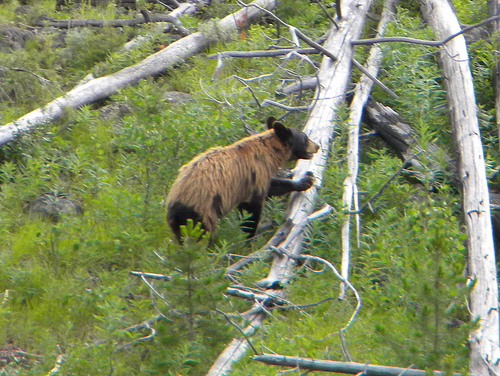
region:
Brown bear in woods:
[165, 112, 319, 250]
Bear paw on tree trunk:
[292, 168, 314, 195]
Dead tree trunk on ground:
[193, 0, 383, 366]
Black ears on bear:
[260, 113, 287, 140]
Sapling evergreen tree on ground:
[145, 218, 232, 357]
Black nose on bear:
[310, 139, 322, 154]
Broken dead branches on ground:
[100, 239, 418, 374]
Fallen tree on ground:
[2, 0, 259, 154]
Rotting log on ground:
[370, 91, 498, 228]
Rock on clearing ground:
[18, 190, 81, 225]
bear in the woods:
[149, 112, 324, 242]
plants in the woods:
[16, 103, 113, 240]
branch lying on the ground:
[248, 336, 405, 374]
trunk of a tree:
[348, 75, 483, 214]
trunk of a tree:
[21, 10, 276, 73]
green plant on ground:
[154, 328, 206, 373]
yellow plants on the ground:
[5, 230, 119, 322]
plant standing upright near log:
[398, 188, 465, 344]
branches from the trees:
[234, 277, 353, 329]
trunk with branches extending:
[222, 13, 462, 96]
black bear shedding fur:
[157, 114, 323, 255]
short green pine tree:
[143, 210, 237, 359]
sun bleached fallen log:
[0, 0, 283, 147]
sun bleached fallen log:
[415, 0, 498, 374]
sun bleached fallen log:
[201, 0, 376, 375]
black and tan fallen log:
[344, 79, 454, 206]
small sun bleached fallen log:
[248, 348, 440, 374]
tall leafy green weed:
[400, 113, 442, 185]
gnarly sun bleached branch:
[192, 38, 324, 143]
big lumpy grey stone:
[20, 184, 92, 229]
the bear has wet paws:
[96, 76, 379, 299]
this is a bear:
[88, 84, 383, 279]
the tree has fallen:
[348, 34, 499, 271]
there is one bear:
[101, 57, 409, 345]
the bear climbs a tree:
[91, 44, 451, 369]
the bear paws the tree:
[93, 51, 358, 298]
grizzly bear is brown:
[67, 8, 362, 288]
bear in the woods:
[95, 69, 367, 294]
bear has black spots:
[111, 6, 418, 313]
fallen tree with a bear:
[85, 59, 360, 299]